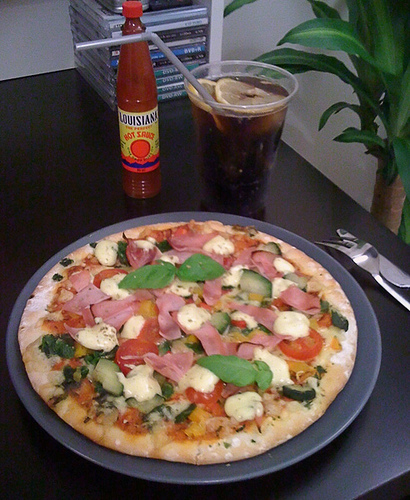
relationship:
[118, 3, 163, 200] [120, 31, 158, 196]
bottle of sauce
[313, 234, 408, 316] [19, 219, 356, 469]
fork next to pizza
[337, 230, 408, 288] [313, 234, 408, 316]
knife next to fork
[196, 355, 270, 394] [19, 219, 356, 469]
basil on pizza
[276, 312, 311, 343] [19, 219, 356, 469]
cheese on pizza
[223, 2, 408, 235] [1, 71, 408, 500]
plant next to table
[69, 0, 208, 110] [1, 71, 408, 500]
stack of cds on table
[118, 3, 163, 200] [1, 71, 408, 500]
bottle of hot sauce on table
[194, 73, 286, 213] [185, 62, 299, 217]
liquid in cup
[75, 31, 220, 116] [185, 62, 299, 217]
straw in cup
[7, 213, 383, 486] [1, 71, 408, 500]
plate on table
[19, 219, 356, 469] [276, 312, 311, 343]
pizza with cheese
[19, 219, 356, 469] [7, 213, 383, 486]
pizza on plate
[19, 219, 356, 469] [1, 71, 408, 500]
pizza on table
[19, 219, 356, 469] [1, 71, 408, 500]
pizza ont table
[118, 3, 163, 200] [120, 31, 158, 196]
bottle of hot sauce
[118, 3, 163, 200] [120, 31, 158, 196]
bottle of louisiana hot sauce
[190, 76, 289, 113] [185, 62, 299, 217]
slices of lemon floating in cup